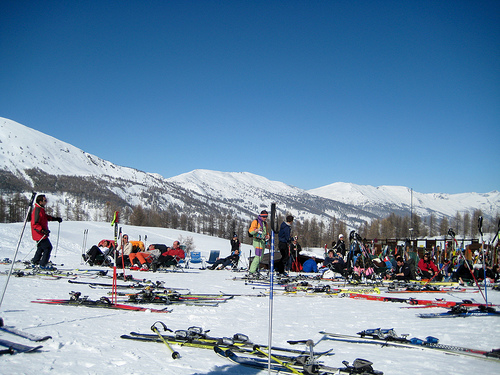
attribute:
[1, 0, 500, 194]
sky — large, blue, daytime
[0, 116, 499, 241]
mountain range — distant, snowy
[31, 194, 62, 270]
man — skiing, skier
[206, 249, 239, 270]
man — sitting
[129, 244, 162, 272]
person — laying, sitting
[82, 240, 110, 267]
person — sitting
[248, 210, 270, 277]
person — skiing, standing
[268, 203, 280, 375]
ski pole — in foreground, thin, metal, blue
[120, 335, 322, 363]
ski — yellow, black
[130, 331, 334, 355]
ski — yellow, black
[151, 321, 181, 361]
ski pole — yellow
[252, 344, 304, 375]
ski pole — yellow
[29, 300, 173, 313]
ski — red, black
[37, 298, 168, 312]
ski — red, black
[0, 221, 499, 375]
ground — snowy, white, snow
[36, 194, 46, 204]
hair — short, black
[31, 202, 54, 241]
jacket — red, gray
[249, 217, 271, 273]
outfit — green, colorful, orange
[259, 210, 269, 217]
hat — purple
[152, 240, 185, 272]
person — sitting, red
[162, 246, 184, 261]
jacket — red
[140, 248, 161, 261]
jacket — white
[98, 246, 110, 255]
jacket — white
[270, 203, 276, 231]
handle — black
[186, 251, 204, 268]
chair — small, blue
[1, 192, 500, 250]
wooded area — brown, bare, nearby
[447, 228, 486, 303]
ski pole — red, vertical, tilted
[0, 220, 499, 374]
skiing area — busy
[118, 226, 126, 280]
ski pole — red, vertical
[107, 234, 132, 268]
person — sitting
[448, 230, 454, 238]
handle — black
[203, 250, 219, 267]
chair — blue